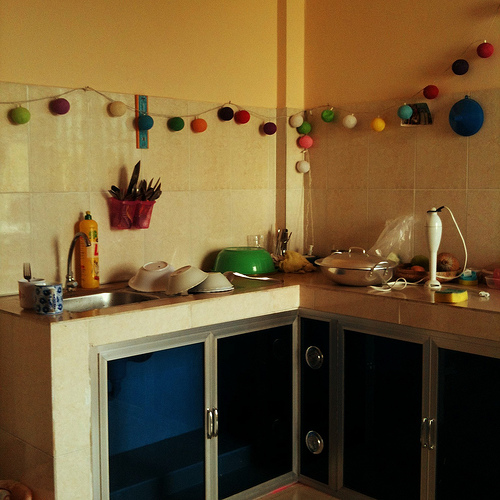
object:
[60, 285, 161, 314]
sink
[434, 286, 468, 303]
sponge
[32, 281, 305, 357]
counter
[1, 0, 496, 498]
kitchen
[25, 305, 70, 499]
corner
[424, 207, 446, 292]
hand mixer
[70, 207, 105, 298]
faucet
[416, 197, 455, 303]
blender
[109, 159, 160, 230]
silverware set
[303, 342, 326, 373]
round object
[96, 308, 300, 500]
cabinet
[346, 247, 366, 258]
handle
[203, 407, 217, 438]
handles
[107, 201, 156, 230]
basket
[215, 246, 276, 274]
green item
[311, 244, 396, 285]
pan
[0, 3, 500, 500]
room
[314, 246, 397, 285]
pot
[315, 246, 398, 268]
lid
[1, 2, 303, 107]
wall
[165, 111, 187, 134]
item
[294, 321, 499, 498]
cabinets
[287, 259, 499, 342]
counter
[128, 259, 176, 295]
bowl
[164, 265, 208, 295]
bowl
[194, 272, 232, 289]
bowl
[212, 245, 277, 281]
bowl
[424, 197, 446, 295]
mixer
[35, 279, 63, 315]
mugs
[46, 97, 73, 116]
items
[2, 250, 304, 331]
counter